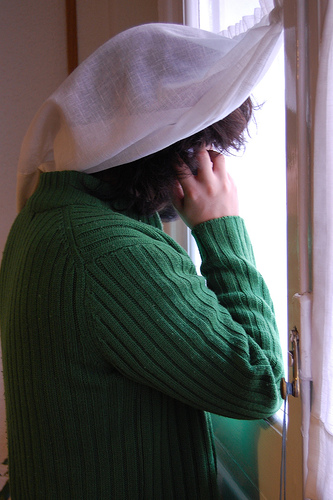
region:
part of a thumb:
[179, 194, 181, 197]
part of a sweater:
[124, 422, 143, 459]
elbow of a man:
[266, 396, 273, 405]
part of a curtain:
[299, 142, 311, 161]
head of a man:
[158, 113, 220, 154]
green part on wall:
[241, 454, 253, 466]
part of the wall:
[251, 444, 265, 461]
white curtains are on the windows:
[192, 0, 321, 498]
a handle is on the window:
[279, 328, 303, 401]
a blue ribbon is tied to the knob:
[281, 379, 290, 499]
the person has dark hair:
[62, 33, 256, 222]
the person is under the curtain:
[20, 5, 273, 490]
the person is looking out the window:
[12, 9, 308, 486]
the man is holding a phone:
[34, 8, 325, 246]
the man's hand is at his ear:
[158, 137, 251, 236]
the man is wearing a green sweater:
[2, 181, 312, 491]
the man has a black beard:
[151, 198, 179, 233]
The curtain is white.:
[210, 45, 255, 70]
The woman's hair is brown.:
[132, 165, 170, 194]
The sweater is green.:
[74, 409, 125, 429]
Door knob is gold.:
[273, 378, 321, 392]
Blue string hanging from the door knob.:
[281, 393, 302, 418]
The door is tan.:
[260, 452, 286, 492]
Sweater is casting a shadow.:
[220, 443, 256, 473]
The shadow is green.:
[227, 433, 251, 456]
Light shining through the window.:
[243, 146, 278, 175]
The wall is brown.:
[17, 59, 69, 82]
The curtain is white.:
[13, 0, 327, 207]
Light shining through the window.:
[181, 0, 287, 311]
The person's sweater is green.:
[0, 177, 285, 493]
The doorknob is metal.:
[273, 322, 297, 398]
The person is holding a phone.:
[162, 130, 235, 221]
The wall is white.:
[0, 0, 71, 244]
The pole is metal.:
[287, 0, 316, 477]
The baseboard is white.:
[204, 427, 267, 499]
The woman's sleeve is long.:
[91, 210, 286, 428]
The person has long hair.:
[77, 88, 265, 213]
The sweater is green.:
[19, 177, 215, 499]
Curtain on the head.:
[80, 9, 240, 206]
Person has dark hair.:
[106, 162, 168, 207]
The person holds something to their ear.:
[180, 135, 208, 176]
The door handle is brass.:
[279, 336, 302, 397]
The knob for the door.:
[280, 376, 299, 400]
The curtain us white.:
[85, 39, 259, 117]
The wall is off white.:
[12, 3, 56, 67]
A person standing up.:
[1, 5, 275, 497]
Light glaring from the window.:
[253, 163, 273, 260]